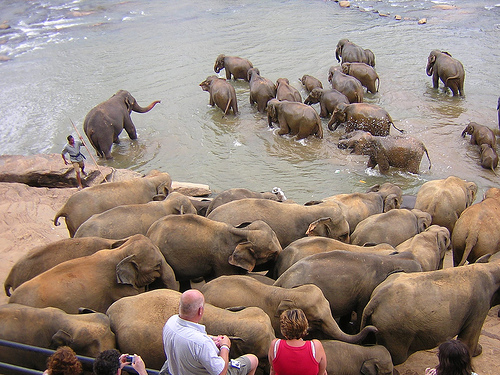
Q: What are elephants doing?
A: Bathing.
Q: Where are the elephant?
A: In the water.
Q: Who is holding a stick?
A: The man.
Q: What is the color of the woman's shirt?
A: Red.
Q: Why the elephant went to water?
A: They are hot.